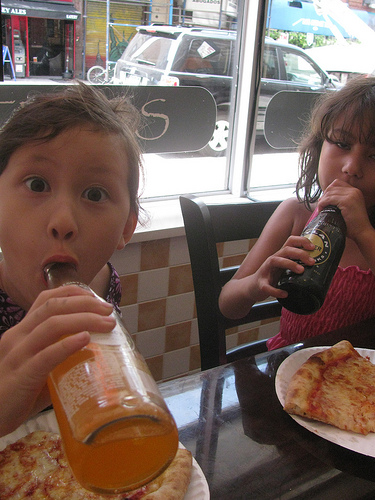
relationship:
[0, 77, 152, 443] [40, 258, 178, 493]
child drinks soda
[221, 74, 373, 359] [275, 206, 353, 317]
girl drinks beer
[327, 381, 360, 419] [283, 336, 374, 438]
melted cheese on pizza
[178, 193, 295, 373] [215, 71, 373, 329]
black chair behind girl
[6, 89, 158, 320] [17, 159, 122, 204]
child has eyes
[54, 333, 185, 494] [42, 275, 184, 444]
soda in bottle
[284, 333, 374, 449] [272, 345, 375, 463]
pizza on paper plate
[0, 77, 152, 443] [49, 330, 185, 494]
child drink soda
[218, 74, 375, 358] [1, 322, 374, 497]
girl at table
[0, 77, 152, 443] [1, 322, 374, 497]
child at table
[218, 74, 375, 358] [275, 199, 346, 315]
girl drinks soda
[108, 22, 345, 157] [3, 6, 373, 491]
car next pizza shop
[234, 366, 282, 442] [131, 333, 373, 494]
shadow on table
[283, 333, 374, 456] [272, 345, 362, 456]
pizza on paper plate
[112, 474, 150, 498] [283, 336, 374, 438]
sauce on pizza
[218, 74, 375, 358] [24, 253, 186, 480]
girl drinking pop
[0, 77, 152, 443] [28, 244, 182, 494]
child has pop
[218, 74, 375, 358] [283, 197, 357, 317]
girl drinks beer